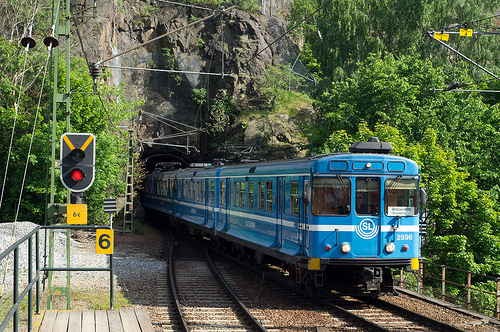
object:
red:
[73, 170, 82, 176]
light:
[72, 169, 82, 179]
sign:
[59, 131, 96, 191]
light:
[340, 241, 350, 254]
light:
[383, 241, 397, 253]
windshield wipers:
[333, 172, 350, 196]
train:
[140, 135, 428, 294]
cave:
[114, 67, 306, 224]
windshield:
[310, 174, 352, 215]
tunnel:
[127, 141, 217, 226]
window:
[386, 178, 418, 215]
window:
[355, 177, 383, 215]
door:
[272, 175, 284, 247]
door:
[218, 175, 232, 234]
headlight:
[365, 161, 371, 167]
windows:
[311, 175, 352, 216]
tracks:
[166, 239, 266, 331]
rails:
[0, 224, 41, 261]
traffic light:
[59, 131, 96, 193]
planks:
[118, 309, 142, 331]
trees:
[0, 0, 149, 229]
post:
[62, 0, 74, 310]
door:
[353, 175, 383, 257]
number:
[395, 233, 402, 241]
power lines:
[230, 0, 334, 73]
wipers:
[383, 174, 403, 195]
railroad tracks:
[213, 246, 465, 331]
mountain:
[0, 0, 500, 224]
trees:
[293, 52, 500, 286]